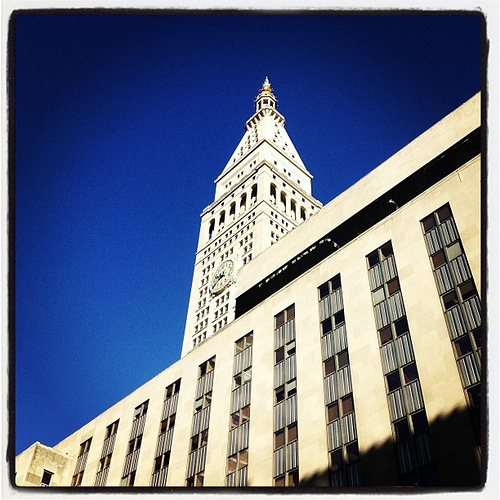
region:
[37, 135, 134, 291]
this is the sky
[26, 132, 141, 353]
the sky is blue in color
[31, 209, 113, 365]
the sky is clear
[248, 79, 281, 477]
this is a building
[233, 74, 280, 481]
the building is tall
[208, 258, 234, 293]
this is a clock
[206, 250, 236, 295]
the clock is big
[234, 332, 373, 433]
there are many windows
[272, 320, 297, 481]
windows arranged in a straight line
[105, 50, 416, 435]
tower behind horizontal building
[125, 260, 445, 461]
rows of double windows on each floor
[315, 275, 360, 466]
ridged squares beneath each window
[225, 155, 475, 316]
partial platform above building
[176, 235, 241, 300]
clock set into side of building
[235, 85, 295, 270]
tiers of corners on tall building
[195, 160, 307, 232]
section of arches with shapes within them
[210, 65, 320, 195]
top of building narrowing to a point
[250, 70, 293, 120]
gold ornamentation near top of building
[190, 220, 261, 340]
sets of three windows across building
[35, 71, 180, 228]
the sky is blue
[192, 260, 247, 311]
this is a clock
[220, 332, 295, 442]
these are windows here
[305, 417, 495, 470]
this is a shadow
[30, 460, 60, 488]
this is a window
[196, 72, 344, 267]
top of the building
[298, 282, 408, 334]
8 windows are visible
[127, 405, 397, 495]
a bunch of windows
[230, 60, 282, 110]
three windows are visible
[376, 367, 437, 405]
these are rectangle windows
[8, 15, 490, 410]
the bright blue sky above the building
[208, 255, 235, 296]
the clock in front of the building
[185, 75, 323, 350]
the tower on top of the building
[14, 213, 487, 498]
a building with a lot of windows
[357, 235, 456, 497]
a row of windows on the building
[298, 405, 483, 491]
a shadow on the building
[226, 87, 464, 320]
a black stripe near the top of the building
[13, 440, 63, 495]
an extra part of the building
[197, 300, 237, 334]
smaller windows on the tower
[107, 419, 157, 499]
more windows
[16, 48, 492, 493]
Building is white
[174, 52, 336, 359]
Building has a tower in the middle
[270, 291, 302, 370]
Window of building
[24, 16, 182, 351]
Sky is blue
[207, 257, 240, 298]
Clock on front of tower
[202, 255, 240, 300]
Clock is white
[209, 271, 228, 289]
Hands of clock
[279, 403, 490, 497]
Shadow on wall of building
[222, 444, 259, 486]
Light can be see inside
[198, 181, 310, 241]
Windows of tower